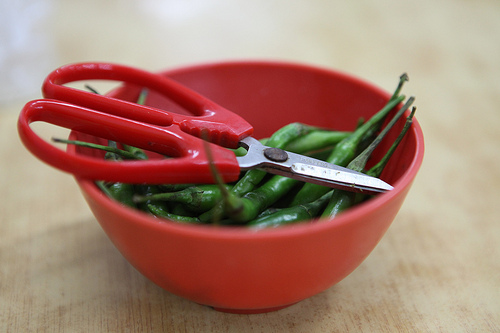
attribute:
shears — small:
[10, 62, 411, 225]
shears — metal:
[23, 44, 395, 221]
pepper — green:
[51, 133, 146, 165]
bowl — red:
[23, 22, 437, 311]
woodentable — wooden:
[434, 52, 472, 139]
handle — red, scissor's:
[87, 130, 257, 223]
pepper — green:
[128, 183, 232, 210]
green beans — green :
[51, 72, 416, 229]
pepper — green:
[146, 201, 197, 223]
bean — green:
[395, 72, 411, 81]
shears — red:
[19, 61, 395, 193]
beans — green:
[52, 73, 415, 228]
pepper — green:
[192, 123, 382, 238]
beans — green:
[253, 82, 404, 228]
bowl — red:
[62, 54, 427, 314]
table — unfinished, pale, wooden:
[380, 17, 491, 154]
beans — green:
[93, 103, 400, 221]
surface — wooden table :
[446, 210, 496, 324]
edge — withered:
[361, 77, 406, 171]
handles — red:
[33, 99, 190, 166]